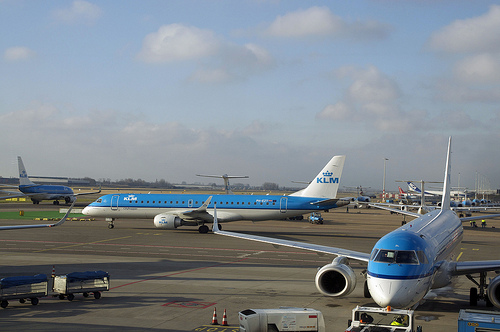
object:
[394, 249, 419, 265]
window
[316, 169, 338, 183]
logo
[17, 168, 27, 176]
logo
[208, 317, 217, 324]
orange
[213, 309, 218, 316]
white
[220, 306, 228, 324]
traffic cone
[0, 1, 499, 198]
sky.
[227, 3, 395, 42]
cloud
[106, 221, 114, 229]
landing gear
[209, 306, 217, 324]
cone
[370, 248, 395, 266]
window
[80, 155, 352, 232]
airplanes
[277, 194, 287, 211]
door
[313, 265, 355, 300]
engine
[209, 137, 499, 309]
plane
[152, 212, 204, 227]
engine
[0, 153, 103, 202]
plane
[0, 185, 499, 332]
runway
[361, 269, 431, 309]
nose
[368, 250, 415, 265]
windshield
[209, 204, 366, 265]
wing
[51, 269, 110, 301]
luggage carts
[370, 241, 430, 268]
cockpit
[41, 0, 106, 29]
cloud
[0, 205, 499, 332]
tarmac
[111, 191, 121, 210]
door